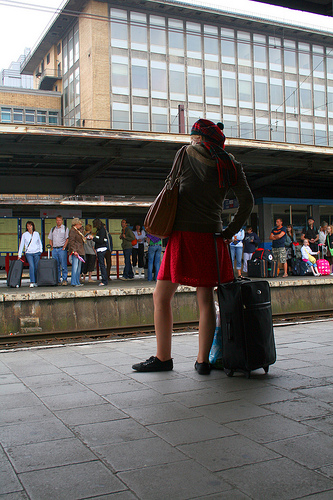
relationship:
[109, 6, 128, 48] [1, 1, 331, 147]
window on building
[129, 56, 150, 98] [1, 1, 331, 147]
window on building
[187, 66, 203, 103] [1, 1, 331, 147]
window on building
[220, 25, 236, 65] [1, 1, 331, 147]
window on building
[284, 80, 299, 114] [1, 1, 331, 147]
window on building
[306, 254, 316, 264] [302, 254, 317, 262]
bag in lap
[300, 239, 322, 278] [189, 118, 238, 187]
girl wearing beanie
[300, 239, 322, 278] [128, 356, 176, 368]
girl wearing black shoes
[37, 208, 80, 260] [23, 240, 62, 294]
man standing behind luggage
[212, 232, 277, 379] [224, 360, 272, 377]
bag on wheels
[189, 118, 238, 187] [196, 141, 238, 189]
beanie matching scarf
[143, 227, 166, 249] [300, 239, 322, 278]
shirt on girl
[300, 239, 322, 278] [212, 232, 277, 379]
girl holding onto bag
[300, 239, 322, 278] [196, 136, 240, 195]
girl wearing scarf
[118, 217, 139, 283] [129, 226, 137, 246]
man wearing backpack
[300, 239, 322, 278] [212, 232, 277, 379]
girl has bag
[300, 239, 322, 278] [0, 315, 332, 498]
girl on platform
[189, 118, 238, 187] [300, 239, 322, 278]
beanie on girl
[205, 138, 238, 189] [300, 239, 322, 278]
scarf on girl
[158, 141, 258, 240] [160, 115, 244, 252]
top on woman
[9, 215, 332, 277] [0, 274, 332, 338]
people on platform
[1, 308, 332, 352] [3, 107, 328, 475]
tracks between platforms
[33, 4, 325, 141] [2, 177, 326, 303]
building above station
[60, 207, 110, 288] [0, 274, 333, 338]
people talking on platform